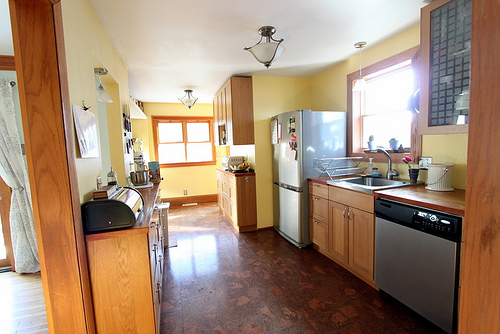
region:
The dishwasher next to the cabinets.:
[371, 199, 455, 323]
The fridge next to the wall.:
[265, 111, 342, 236]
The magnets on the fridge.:
[265, 115, 297, 162]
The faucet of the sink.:
[378, 145, 395, 181]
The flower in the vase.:
[402, 155, 416, 167]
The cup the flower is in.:
[409, 165, 418, 182]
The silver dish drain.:
[310, 152, 367, 177]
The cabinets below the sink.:
[328, 202, 375, 281]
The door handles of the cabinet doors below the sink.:
[342, 206, 352, 218]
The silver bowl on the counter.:
[128, 165, 151, 184]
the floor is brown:
[224, 272, 339, 333]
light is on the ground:
[180, 226, 237, 264]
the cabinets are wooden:
[314, 189, 374, 263]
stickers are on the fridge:
[281, 116, 300, 168]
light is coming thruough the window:
[157, 110, 220, 170]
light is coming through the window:
[356, 77, 416, 153]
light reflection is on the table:
[308, 116, 348, 153]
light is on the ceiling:
[248, 36, 295, 80]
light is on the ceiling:
[178, 94, 204, 114]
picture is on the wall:
[76, 103, 108, 163]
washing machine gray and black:
[375, 192, 461, 332]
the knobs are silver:
[417, 210, 452, 223]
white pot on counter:
[425, 160, 452, 190]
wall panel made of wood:
[8, 0, 93, 332]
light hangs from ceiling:
[242, 24, 280, 68]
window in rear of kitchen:
[152, 113, 214, 165]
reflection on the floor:
[161, 229, 242, 279]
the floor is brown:
[162, 203, 440, 332]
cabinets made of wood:
[308, 179, 373, 288]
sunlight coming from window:
[349, 63, 414, 150]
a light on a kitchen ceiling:
[248, 25, 287, 72]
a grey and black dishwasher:
[370, 189, 459, 331]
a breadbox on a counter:
[84, 184, 145, 233]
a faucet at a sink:
[366, 145, 399, 178]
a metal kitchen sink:
[337, 170, 409, 192]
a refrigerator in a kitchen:
[262, 104, 349, 251]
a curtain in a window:
[0, 79, 41, 278]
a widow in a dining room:
[154, 112, 218, 170]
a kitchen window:
[342, 49, 427, 154]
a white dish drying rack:
[314, 150, 367, 184]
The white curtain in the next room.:
[4, 79, 44, 275]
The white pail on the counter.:
[424, 158, 455, 193]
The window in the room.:
[155, 118, 215, 163]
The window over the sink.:
[349, 65, 426, 164]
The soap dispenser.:
[366, 153, 376, 175]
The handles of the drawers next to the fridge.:
[310, 180, 320, 226]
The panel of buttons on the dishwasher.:
[412, 206, 453, 233]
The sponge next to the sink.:
[371, 169, 381, 178]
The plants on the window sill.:
[365, 137, 405, 154]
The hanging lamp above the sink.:
[349, 40, 369, 92]